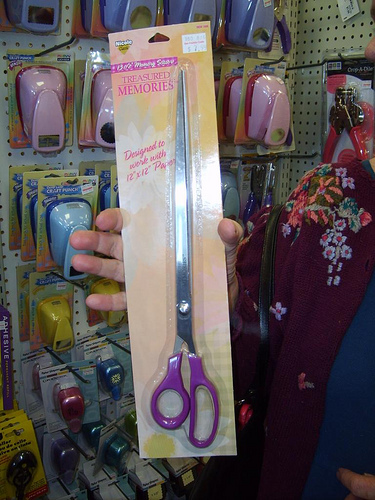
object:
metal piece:
[177, 300, 190, 314]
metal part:
[322, 87, 368, 165]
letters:
[118, 87, 127, 97]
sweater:
[227, 156, 374, 500]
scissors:
[148, 69, 219, 445]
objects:
[4, 0, 62, 35]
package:
[105, 21, 237, 458]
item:
[14, 64, 67, 155]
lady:
[67, 162, 374, 500]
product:
[44, 195, 93, 281]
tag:
[182, 33, 207, 54]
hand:
[70, 207, 244, 310]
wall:
[0, 0, 297, 500]